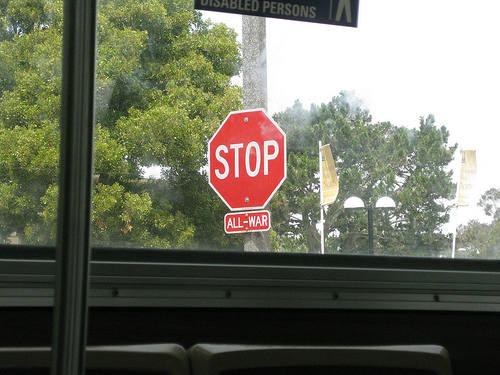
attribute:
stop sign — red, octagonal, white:
[205, 106, 287, 210]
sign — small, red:
[222, 209, 272, 234]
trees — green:
[0, 0, 498, 257]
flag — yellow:
[318, 143, 340, 208]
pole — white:
[317, 137, 325, 254]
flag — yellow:
[456, 146, 478, 209]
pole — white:
[449, 144, 460, 257]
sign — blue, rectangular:
[194, 1, 361, 28]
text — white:
[200, 1, 315, 21]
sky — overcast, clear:
[137, 0, 498, 236]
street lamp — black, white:
[341, 193, 398, 255]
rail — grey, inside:
[51, 1, 98, 374]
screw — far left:
[109, 284, 120, 301]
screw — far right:
[431, 291, 439, 303]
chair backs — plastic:
[1, 338, 455, 374]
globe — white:
[373, 193, 396, 212]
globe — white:
[339, 195, 365, 210]